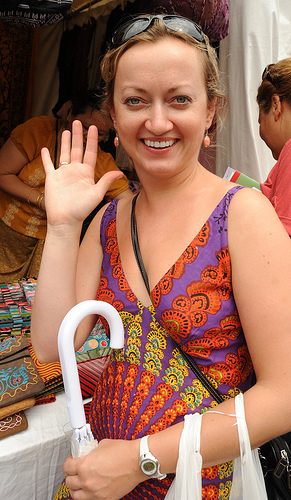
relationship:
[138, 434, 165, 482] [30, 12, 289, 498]
watch on woman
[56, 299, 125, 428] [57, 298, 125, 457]
handle of umbrella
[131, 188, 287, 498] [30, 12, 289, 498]
purse with woman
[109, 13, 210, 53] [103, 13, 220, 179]
sunglasses on head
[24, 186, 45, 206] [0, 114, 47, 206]
ring bracelet on woman's arm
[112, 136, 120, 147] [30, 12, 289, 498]
earring on woman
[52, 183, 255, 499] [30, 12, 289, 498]
dress on woman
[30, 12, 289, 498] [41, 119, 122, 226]
woman waving hand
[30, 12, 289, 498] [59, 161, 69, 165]
woman wearing ring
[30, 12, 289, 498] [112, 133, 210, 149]
woman wearing earrings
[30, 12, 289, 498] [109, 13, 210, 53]
woman with sunglasses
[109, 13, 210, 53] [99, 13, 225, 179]
sunglasses on head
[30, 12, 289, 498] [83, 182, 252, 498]
woman wearing dress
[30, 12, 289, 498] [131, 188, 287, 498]
woman wearing purse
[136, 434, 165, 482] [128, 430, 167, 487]
watch on wrist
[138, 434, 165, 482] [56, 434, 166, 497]
watch on hand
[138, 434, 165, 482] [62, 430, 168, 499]
watch on hand